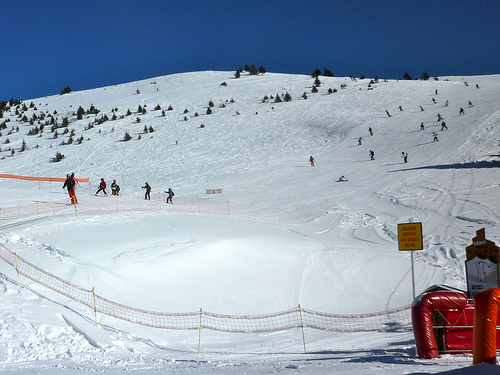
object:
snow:
[3, 69, 498, 374]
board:
[398, 221, 423, 251]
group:
[61, 170, 173, 207]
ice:
[6, 200, 430, 319]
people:
[59, 169, 81, 206]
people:
[92, 173, 109, 197]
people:
[108, 178, 123, 199]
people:
[139, 180, 154, 201]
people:
[160, 185, 180, 209]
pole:
[404, 255, 422, 291]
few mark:
[12, 303, 103, 369]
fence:
[193, 302, 318, 347]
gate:
[3, 285, 420, 358]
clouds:
[5, 5, 496, 100]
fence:
[0, 198, 414, 354]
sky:
[0, 0, 500, 103]